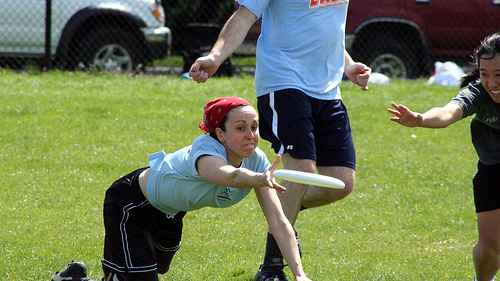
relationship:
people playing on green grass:
[80, 70, 498, 198] [26, 110, 117, 148]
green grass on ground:
[26, 110, 117, 148] [391, 227, 460, 260]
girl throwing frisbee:
[52, 93, 312, 280] [271, 164, 349, 194]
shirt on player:
[233, 0, 350, 97] [183, 0, 375, 277]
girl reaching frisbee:
[52, 96, 312, 281] [268, 159, 345, 192]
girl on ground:
[52, 96, 312, 281] [1, 50, 498, 278]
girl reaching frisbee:
[52, 96, 312, 281] [274, 165, 353, 191]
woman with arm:
[385, 31, 499, 278] [386, 80, 478, 131]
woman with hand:
[385, 31, 499, 278] [386, 100, 424, 129]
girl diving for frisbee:
[52, 96, 312, 281] [228, 161, 376, 215]